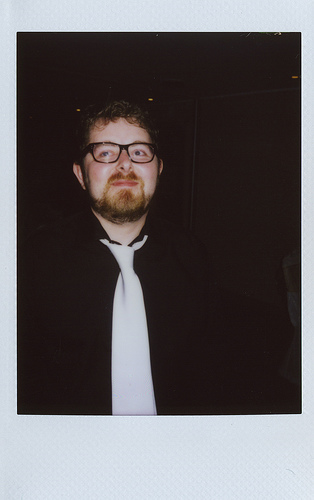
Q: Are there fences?
A: No, there are no fences.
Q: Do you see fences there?
A: No, there are no fences.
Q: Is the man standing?
A: Yes, the man is standing.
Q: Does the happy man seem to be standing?
A: Yes, the man is standing.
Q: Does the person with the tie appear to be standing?
A: Yes, the man is standing.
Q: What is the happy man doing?
A: The man is standing.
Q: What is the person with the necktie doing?
A: The man is standing.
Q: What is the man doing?
A: The man is standing.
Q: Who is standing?
A: The man is standing.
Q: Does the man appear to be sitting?
A: No, the man is standing.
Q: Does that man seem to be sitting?
A: No, the man is standing.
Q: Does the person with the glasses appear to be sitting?
A: No, the man is standing.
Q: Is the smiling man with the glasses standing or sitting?
A: The man is standing.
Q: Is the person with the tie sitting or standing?
A: The man is standing.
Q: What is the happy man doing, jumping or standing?
A: The man is standing.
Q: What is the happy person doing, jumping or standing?
A: The man is standing.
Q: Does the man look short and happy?
A: Yes, the man is short and happy.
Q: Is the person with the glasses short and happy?
A: Yes, the man is short and happy.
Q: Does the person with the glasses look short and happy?
A: Yes, the man is short and happy.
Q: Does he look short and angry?
A: No, the man is short but happy.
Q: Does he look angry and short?
A: No, the man is short but happy.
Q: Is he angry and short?
A: No, the man is short but happy.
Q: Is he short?
A: Yes, the man is short.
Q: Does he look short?
A: Yes, the man is short.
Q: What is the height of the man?
A: The man is short.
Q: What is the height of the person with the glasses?
A: The man is short.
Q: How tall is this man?
A: The man is short.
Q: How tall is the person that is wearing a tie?
A: The man is short.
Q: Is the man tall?
A: No, the man is short.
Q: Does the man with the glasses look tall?
A: No, the man is short.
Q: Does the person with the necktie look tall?
A: No, the man is short.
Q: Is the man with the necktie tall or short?
A: The man is short.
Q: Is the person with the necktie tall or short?
A: The man is short.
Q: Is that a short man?
A: Yes, that is a short man.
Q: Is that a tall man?
A: No, that is a short man.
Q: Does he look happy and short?
A: Yes, the man is happy and short.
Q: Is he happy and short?
A: Yes, the man is happy and short.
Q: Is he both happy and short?
A: Yes, the man is happy and short.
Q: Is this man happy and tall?
A: No, the man is happy but short.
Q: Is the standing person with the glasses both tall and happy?
A: No, the man is happy but short.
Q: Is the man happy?
A: Yes, the man is happy.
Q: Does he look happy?
A: Yes, the man is happy.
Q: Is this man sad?
A: No, the man is happy.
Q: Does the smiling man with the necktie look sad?
A: No, the man is happy.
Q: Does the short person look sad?
A: No, the man is happy.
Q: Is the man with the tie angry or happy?
A: The man is happy.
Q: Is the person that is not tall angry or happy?
A: The man is happy.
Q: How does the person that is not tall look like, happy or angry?
A: The man is happy.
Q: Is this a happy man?
A: Yes, this is a happy man.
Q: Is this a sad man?
A: No, this is a happy man.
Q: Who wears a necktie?
A: The man wears a necktie.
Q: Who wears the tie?
A: The man wears a necktie.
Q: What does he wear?
A: The man wears a necktie.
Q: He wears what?
A: The man wears a necktie.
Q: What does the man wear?
A: The man wears a necktie.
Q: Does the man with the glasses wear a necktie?
A: Yes, the man wears a necktie.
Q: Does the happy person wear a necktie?
A: Yes, the man wears a necktie.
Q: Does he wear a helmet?
A: No, the man wears a necktie.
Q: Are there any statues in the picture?
A: No, there are no statues.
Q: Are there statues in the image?
A: No, there are no statues.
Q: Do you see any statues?
A: No, there are no statues.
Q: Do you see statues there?
A: No, there are no statues.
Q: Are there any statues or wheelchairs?
A: No, there are no statues or wheelchairs.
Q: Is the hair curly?
A: Yes, the hair is curly.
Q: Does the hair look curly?
A: Yes, the hair is curly.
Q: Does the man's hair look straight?
A: No, the hair is curly.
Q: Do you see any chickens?
A: No, there are no chickens.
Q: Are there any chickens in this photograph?
A: No, there are no chickens.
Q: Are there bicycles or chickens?
A: No, there are no chickens or bicycles.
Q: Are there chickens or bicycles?
A: No, there are no chickens or bicycles.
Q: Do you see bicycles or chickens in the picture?
A: No, there are no chickens or bicycles.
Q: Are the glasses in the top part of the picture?
A: Yes, the glasses are in the top of the image.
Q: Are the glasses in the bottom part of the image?
A: No, the glasses are in the top of the image.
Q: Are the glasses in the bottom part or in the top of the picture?
A: The glasses are in the top of the image.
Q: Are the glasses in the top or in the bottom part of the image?
A: The glasses are in the top of the image.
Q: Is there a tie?
A: Yes, there is a tie.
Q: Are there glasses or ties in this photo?
A: Yes, there is a tie.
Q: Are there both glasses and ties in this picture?
A: Yes, there are both a tie and glasses.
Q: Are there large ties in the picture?
A: Yes, there is a large tie.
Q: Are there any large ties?
A: Yes, there is a large tie.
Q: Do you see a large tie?
A: Yes, there is a large tie.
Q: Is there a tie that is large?
A: Yes, there is a tie that is large.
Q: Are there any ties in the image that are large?
A: Yes, there is a tie that is large.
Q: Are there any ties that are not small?
A: Yes, there is a large tie.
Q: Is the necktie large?
A: Yes, the necktie is large.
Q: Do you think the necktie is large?
A: Yes, the necktie is large.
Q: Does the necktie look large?
A: Yes, the necktie is large.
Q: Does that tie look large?
A: Yes, the tie is large.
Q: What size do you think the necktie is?
A: The necktie is large.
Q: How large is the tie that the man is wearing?
A: The necktie is large.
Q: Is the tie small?
A: No, the tie is large.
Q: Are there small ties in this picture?
A: No, there is a tie but it is large.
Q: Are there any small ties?
A: No, there is a tie but it is large.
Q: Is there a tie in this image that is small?
A: No, there is a tie but it is large.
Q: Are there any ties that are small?
A: No, there is a tie but it is large.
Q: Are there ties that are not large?
A: No, there is a tie but it is large.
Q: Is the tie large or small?
A: The tie is large.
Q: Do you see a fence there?
A: No, there are no fences.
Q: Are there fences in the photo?
A: No, there are no fences.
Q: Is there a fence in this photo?
A: No, there are no fences.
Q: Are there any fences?
A: No, there are no fences.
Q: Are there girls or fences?
A: No, there are no fences or girls.